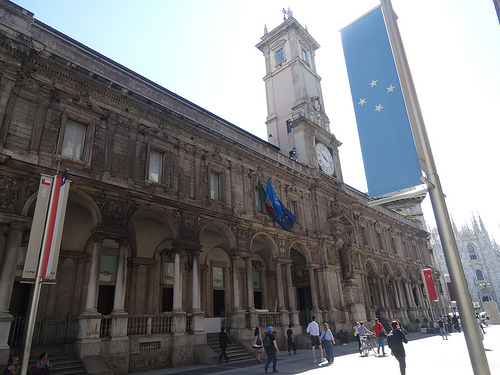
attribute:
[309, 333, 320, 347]
dark shorts — black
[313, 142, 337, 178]
clock face — white, round, large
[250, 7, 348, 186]
clock tower — gray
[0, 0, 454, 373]
building — old, stone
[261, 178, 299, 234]
flag — blue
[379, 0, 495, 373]
pole — metal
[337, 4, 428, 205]
banner — blue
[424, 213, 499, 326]
cathedral — gothic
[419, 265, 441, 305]
banner — red, gold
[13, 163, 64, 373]
pole — metal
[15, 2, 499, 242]
sky — blue